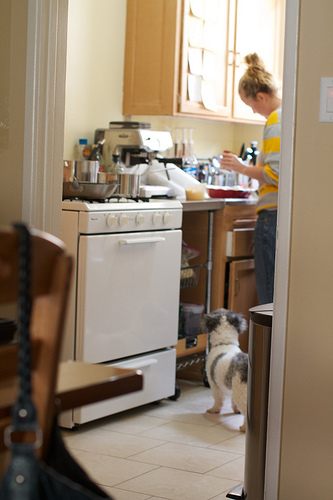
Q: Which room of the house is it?
A: It is a kitchen.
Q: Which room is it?
A: It is a kitchen.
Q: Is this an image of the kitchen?
A: Yes, it is showing the kitchen.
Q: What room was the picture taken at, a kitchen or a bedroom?
A: It was taken at a kitchen.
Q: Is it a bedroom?
A: No, it is a kitchen.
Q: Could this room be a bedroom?
A: No, it is a kitchen.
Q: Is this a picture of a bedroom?
A: No, the picture is showing a kitchen.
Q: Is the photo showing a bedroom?
A: No, the picture is showing a kitchen.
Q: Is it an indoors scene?
A: Yes, it is indoors.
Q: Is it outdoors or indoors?
A: It is indoors.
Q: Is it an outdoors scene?
A: No, it is indoors.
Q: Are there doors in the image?
A: Yes, there is a door.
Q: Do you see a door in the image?
A: Yes, there is a door.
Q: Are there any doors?
A: Yes, there is a door.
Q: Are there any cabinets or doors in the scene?
A: Yes, there is a door.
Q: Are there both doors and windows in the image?
A: No, there is a door but no windows.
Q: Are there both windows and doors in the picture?
A: No, there is a door but no windows.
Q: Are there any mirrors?
A: No, there are no mirrors.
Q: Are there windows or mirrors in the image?
A: No, there are no mirrors or windows.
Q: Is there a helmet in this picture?
A: No, there are no helmets.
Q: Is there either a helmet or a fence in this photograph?
A: No, there are no helmets or fences.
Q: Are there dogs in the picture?
A: Yes, there is a dog.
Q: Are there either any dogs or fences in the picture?
A: Yes, there is a dog.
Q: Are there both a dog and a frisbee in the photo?
A: No, there is a dog but no frisbees.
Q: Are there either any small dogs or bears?
A: Yes, there is a small dog.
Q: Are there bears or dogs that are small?
A: Yes, the dog is small.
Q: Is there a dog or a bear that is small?
A: Yes, the dog is small.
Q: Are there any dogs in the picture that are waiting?
A: Yes, there is a dog that is waiting.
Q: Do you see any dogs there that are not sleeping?
A: Yes, there is a dog that is waiting .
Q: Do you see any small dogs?
A: Yes, there is a small dog.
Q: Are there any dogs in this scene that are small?
A: Yes, there is a dog that is small.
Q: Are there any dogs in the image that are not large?
A: Yes, there is a small dog.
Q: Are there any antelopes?
A: No, there are no antelopes.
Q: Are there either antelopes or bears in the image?
A: No, there are no antelopes or bears.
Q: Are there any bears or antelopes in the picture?
A: No, there are no antelopes or bears.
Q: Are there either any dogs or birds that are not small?
A: No, there is a dog but it is small.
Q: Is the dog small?
A: Yes, the dog is small.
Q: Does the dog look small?
A: Yes, the dog is small.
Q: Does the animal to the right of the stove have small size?
A: Yes, the dog is small.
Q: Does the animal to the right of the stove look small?
A: Yes, the dog is small.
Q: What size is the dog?
A: The dog is small.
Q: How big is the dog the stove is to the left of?
A: The dog is small.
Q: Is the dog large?
A: No, the dog is small.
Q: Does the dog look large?
A: No, the dog is small.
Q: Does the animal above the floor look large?
A: No, the dog is small.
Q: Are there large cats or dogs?
A: No, there is a dog but it is small.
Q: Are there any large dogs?
A: No, there is a dog but it is small.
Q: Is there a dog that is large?
A: No, there is a dog but it is small.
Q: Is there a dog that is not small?
A: No, there is a dog but it is small.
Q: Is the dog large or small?
A: The dog is small.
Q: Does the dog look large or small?
A: The dog is small.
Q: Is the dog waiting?
A: Yes, the dog is waiting.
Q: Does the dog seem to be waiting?
A: Yes, the dog is waiting.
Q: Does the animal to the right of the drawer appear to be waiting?
A: Yes, the dog is waiting.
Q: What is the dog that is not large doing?
A: The dog is waiting.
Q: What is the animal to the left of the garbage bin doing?
A: The dog is waiting.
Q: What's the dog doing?
A: The dog is waiting.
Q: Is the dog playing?
A: No, the dog is waiting.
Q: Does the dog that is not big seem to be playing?
A: No, the dog is waiting.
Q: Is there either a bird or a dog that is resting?
A: No, there is a dog but it is waiting.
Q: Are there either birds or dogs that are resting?
A: No, there is a dog but it is waiting.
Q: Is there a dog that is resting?
A: No, there is a dog but it is waiting.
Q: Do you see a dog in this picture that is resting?
A: No, there is a dog but it is waiting.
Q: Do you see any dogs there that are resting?
A: No, there is a dog but it is waiting.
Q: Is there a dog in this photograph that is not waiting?
A: No, there is a dog but it is waiting.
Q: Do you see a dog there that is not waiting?
A: No, there is a dog but it is waiting.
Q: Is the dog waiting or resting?
A: The dog is waiting.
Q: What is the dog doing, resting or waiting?
A: The dog is waiting.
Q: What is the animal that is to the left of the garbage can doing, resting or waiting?
A: The dog is waiting.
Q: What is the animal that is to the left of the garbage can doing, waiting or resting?
A: The dog is waiting.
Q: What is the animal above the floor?
A: The animal is a dog.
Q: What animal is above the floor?
A: The animal is a dog.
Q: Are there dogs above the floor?
A: Yes, there is a dog above the floor.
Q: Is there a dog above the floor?
A: Yes, there is a dog above the floor.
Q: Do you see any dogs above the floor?
A: Yes, there is a dog above the floor.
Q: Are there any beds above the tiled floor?
A: No, there is a dog above the floor.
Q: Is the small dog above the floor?
A: Yes, the dog is above the floor.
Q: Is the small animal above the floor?
A: Yes, the dog is above the floor.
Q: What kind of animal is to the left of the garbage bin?
A: The animal is a dog.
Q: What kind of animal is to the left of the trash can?
A: The animal is a dog.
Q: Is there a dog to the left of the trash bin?
A: Yes, there is a dog to the left of the trash bin.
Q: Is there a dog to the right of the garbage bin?
A: No, the dog is to the left of the garbage bin.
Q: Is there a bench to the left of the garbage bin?
A: No, there is a dog to the left of the garbage bin.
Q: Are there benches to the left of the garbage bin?
A: No, there is a dog to the left of the garbage bin.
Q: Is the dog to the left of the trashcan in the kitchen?
A: Yes, the dog is to the left of the garbage can.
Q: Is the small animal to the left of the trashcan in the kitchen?
A: Yes, the dog is to the left of the garbage can.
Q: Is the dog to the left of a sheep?
A: No, the dog is to the left of the garbage can.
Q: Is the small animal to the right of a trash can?
A: No, the dog is to the left of a trash can.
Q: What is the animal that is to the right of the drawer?
A: The animal is a dog.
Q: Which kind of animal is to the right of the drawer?
A: The animal is a dog.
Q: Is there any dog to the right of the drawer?
A: Yes, there is a dog to the right of the drawer.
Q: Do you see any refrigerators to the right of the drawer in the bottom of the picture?
A: No, there is a dog to the right of the drawer.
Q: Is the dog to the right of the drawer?
A: Yes, the dog is to the right of the drawer.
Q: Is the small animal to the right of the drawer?
A: Yes, the dog is to the right of the drawer.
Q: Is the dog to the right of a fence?
A: No, the dog is to the right of the drawer.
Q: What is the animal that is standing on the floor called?
A: The animal is a dog.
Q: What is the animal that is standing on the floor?
A: The animal is a dog.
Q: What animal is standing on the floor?
A: The animal is a dog.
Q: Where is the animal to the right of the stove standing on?
A: The dog is standing on the floor.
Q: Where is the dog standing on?
A: The dog is standing on the floor.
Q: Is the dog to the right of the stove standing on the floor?
A: Yes, the dog is standing on the floor.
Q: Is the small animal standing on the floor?
A: Yes, the dog is standing on the floor.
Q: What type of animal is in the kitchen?
A: The animal is a dog.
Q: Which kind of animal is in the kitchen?
A: The animal is a dog.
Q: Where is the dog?
A: The dog is in the kitchen.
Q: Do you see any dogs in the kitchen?
A: Yes, there is a dog in the kitchen.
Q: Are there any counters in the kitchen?
A: No, there is a dog in the kitchen.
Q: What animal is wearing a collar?
A: The animal is a dog.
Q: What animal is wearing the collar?
A: The animal is a dog.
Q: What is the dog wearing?
A: The dog is wearing a collar.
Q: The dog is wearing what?
A: The dog is wearing a collar.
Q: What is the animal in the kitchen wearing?
A: The dog is wearing a collar.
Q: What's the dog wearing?
A: The dog is wearing a collar.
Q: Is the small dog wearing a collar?
A: Yes, the dog is wearing a collar.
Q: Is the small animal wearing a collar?
A: Yes, the dog is wearing a collar.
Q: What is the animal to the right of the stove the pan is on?
A: The animal is a dog.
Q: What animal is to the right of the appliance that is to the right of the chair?
A: The animal is a dog.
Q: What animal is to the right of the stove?
A: The animal is a dog.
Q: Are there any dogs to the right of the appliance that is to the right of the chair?
A: Yes, there is a dog to the right of the stove.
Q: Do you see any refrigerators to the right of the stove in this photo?
A: No, there is a dog to the right of the stove.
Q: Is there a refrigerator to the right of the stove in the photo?
A: No, there is a dog to the right of the stove.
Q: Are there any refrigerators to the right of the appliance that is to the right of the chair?
A: No, there is a dog to the right of the stove.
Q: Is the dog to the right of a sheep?
A: No, the dog is to the right of the stove.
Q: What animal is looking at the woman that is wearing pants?
A: The dog is looking at the woman.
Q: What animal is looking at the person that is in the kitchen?
A: The dog is looking at the woman.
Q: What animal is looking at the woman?
A: The dog is looking at the woman.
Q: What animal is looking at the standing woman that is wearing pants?
A: The animal is a dog.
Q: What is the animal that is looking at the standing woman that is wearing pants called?
A: The animal is a dog.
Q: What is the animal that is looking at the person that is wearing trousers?
A: The animal is a dog.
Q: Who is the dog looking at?
A: The dog is looking at the woman.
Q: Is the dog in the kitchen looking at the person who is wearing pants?
A: Yes, the dog is looking at the woman.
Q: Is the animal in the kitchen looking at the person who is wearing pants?
A: Yes, the dog is looking at the woman.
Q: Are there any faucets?
A: No, there are no faucets.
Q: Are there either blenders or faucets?
A: No, there are no faucets or blenders.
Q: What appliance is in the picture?
A: The appliance is a stove.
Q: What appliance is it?
A: The appliance is a stove.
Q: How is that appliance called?
A: This is a stove.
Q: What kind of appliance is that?
A: This is a stove.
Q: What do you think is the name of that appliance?
A: This is a stove.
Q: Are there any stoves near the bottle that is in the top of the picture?
A: Yes, there is a stove near the bottle.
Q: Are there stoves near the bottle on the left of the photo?
A: Yes, there is a stove near the bottle.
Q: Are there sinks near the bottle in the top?
A: No, there is a stove near the bottle.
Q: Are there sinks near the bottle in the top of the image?
A: No, there is a stove near the bottle.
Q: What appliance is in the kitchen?
A: The appliance is a stove.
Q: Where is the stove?
A: The stove is in the kitchen.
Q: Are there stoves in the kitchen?
A: Yes, there is a stove in the kitchen.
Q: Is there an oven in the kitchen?
A: No, there is a stove in the kitchen.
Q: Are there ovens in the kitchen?
A: No, there is a stove in the kitchen.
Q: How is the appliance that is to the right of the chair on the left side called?
A: The appliance is a stove.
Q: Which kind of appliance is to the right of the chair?
A: The appliance is a stove.